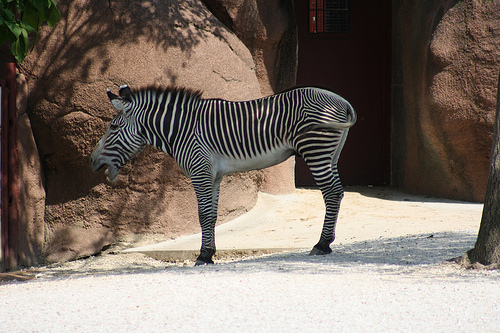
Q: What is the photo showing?
A: It is showing a pen.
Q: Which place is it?
A: It is a pen.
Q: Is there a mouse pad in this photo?
A: No, there are no mouse pads.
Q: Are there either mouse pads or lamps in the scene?
A: No, there are no mouse pads or lamps.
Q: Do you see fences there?
A: No, there are no fences.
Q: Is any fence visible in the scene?
A: No, there are no fences.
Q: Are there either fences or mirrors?
A: No, there are no fences or mirrors.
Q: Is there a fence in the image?
A: No, there are no fences.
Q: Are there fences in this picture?
A: No, there are no fences.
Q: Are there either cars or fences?
A: No, there are no fences or cars.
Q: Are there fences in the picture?
A: No, there are no fences.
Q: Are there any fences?
A: No, there are no fences.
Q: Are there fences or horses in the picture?
A: No, there are no fences or horses.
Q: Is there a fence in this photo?
A: No, there are no fences.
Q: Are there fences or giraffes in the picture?
A: No, there are no fences or giraffes.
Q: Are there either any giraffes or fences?
A: No, there are no fences or giraffes.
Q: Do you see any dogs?
A: No, there are no dogs.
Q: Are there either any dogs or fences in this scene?
A: No, there are no dogs or fences.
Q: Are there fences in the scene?
A: No, there are no fences.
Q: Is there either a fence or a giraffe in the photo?
A: No, there are no fences or giraffes.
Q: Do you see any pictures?
A: No, there are no pictures.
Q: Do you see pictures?
A: No, there are no pictures.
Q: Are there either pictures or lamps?
A: No, there are no pictures or lamps.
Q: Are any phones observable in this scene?
A: No, there are no phones.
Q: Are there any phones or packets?
A: No, there are no phones or packets.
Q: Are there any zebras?
A: Yes, there is a zebra.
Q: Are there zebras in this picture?
A: Yes, there is a zebra.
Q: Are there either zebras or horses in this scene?
A: Yes, there is a zebra.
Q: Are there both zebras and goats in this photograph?
A: No, there is a zebra but no goats.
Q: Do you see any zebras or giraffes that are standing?
A: Yes, the zebra is standing.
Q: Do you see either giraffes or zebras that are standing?
A: Yes, the zebra is standing.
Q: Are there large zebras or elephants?
A: Yes, there is a large zebra.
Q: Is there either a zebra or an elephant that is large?
A: Yes, the zebra is large.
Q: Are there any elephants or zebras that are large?
A: Yes, the zebra is large.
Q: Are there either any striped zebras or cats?
A: Yes, there is a striped zebra.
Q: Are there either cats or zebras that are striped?
A: Yes, the zebra is striped.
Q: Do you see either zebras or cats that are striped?
A: Yes, the zebra is striped.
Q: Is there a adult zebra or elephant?
A: Yes, there is an adult zebra.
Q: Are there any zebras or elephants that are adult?
A: Yes, the zebra is adult.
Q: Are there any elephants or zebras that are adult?
A: Yes, the zebra is adult.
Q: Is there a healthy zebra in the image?
A: Yes, there is a healthy zebra.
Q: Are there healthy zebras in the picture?
A: Yes, there is a healthy zebra.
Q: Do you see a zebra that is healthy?
A: Yes, there is a zebra that is healthy.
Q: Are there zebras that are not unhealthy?
A: Yes, there is an healthy zebra.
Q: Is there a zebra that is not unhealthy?
A: Yes, there is an healthy zebra.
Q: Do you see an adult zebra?
A: Yes, there is an adult zebra.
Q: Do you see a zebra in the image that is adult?
A: Yes, there is a zebra that is adult.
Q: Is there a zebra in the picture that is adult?
A: Yes, there is a zebra that is adult.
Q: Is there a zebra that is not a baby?
A: Yes, there is a adult zebra.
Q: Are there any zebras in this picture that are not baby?
A: Yes, there is a adult zebra.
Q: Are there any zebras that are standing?
A: Yes, there is a zebra that is standing.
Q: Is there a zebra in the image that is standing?
A: Yes, there is a zebra that is standing.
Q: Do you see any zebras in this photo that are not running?
A: Yes, there is a zebra that is standing .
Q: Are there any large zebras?
A: Yes, there is a large zebra.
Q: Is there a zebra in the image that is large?
A: Yes, there is a zebra that is large.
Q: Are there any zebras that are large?
A: Yes, there is a zebra that is large.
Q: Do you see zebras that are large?
A: Yes, there is a zebra that is large.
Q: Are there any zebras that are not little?
A: Yes, there is a large zebra.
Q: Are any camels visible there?
A: No, there are no camels.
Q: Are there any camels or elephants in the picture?
A: No, there are no camels or elephants.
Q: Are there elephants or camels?
A: No, there are no camels or elephants.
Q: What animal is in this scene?
A: The animal is a zebra.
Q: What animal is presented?
A: The animal is a zebra.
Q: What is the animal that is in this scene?
A: The animal is a zebra.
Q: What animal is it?
A: The animal is a zebra.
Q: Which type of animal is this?
A: This is a zebra.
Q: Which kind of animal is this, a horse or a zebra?
A: This is a zebra.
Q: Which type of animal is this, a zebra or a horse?
A: This is a zebra.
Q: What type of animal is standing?
A: The animal is a zebra.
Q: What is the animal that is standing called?
A: The animal is a zebra.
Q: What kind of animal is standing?
A: The animal is a zebra.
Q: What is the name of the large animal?
A: The animal is a zebra.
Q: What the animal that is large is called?
A: The animal is a zebra.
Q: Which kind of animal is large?
A: The animal is a zebra.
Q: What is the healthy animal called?
A: The animal is a zebra.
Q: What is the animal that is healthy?
A: The animal is a zebra.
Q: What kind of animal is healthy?
A: The animal is a zebra.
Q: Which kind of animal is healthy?
A: The animal is a zebra.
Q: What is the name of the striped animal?
A: The animal is a zebra.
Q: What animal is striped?
A: The animal is a zebra.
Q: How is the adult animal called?
A: The animal is a zebra.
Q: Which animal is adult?
A: The animal is a zebra.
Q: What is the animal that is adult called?
A: The animal is a zebra.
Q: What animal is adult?
A: The animal is a zebra.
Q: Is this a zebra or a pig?
A: This is a zebra.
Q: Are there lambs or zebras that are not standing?
A: No, there is a zebra but it is standing.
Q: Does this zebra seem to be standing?
A: Yes, the zebra is standing.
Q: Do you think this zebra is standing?
A: Yes, the zebra is standing.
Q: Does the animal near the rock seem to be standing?
A: Yes, the zebra is standing.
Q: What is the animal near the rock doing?
A: The zebra is standing.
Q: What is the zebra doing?
A: The zebra is standing.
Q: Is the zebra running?
A: No, the zebra is standing.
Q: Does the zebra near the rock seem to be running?
A: No, the zebra is standing.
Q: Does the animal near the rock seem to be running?
A: No, the zebra is standing.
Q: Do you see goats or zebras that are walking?
A: No, there is a zebra but it is standing.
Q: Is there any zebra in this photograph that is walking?
A: No, there is a zebra but it is standing.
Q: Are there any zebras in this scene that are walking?
A: No, there is a zebra but it is standing.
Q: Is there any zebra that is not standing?
A: No, there is a zebra but it is standing.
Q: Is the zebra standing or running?
A: The zebra is standing.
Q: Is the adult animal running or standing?
A: The zebra is standing.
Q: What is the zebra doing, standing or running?
A: The zebra is standing.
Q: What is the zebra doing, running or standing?
A: The zebra is standing.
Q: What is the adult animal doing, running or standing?
A: The zebra is standing.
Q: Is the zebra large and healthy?
A: Yes, the zebra is large and healthy.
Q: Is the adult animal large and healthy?
A: Yes, the zebra is large and healthy.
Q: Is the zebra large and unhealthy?
A: No, the zebra is large but healthy.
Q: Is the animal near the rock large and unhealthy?
A: No, the zebra is large but healthy.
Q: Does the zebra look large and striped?
A: Yes, the zebra is large and striped.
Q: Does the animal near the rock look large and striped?
A: Yes, the zebra is large and striped.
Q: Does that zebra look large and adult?
A: Yes, the zebra is large and adult.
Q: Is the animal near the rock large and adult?
A: Yes, the zebra is large and adult.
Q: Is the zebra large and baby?
A: No, the zebra is large but adult.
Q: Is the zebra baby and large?
A: No, the zebra is large but adult.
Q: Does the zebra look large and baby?
A: No, the zebra is large but adult.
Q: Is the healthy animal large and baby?
A: No, the zebra is large but adult.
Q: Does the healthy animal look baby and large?
A: No, the zebra is large but adult.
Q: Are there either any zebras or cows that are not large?
A: No, there is a zebra but it is large.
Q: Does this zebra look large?
A: Yes, the zebra is large.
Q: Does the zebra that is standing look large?
A: Yes, the zebra is large.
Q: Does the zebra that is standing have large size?
A: Yes, the zebra is large.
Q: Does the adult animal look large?
A: Yes, the zebra is large.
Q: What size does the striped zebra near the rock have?
A: The zebra has large size.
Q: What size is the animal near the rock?
A: The zebra is large.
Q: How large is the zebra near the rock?
A: The zebra is large.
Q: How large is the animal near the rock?
A: The zebra is large.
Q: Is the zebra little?
A: No, the zebra is large.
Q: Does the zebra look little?
A: No, the zebra is large.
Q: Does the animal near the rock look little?
A: No, the zebra is large.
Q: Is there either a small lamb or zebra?
A: No, there is a zebra but it is large.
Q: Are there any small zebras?
A: No, there is a zebra but it is large.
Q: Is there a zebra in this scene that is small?
A: No, there is a zebra but it is large.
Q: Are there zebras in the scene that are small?
A: No, there is a zebra but it is large.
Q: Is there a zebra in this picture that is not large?
A: No, there is a zebra but it is large.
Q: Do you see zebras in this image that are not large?
A: No, there is a zebra but it is large.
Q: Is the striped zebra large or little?
A: The zebra is large.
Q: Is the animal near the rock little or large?
A: The zebra is large.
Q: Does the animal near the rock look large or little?
A: The zebra is large.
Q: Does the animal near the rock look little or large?
A: The zebra is large.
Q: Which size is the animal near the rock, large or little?
A: The zebra is large.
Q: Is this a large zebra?
A: Yes, this is a large zebra.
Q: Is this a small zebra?
A: No, this is a large zebra.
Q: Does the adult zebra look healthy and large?
A: Yes, the zebra is healthy and large.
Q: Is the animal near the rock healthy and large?
A: Yes, the zebra is healthy and large.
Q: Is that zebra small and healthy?
A: No, the zebra is healthy but large.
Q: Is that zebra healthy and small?
A: No, the zebra is healthy but large.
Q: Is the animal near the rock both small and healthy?
A: No, the zebra is healthy but large.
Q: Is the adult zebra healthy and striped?
A: Yes, the zebra is healthy and striped.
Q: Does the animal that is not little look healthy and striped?
A: Yes, the zebra is healthy and striped.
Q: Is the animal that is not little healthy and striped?
A: Yes, the zebra is healthy and striped.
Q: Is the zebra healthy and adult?
A: Yes, the zebra is healthy and adult.